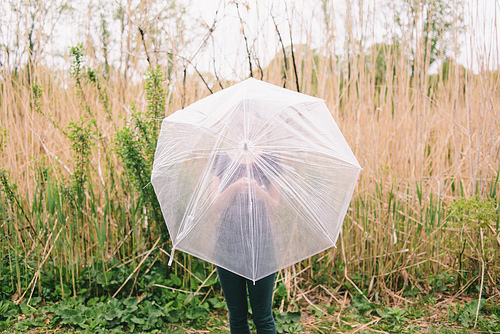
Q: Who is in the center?
A: A woman.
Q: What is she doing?
A: Holding an umbrella.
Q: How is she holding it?
A: In front of her with both hands.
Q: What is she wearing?
A: Jeans and a short-sleeve top.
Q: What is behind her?
A: Vegetation.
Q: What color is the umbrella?
A: It is translucent white.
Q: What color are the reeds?
A: Tan.